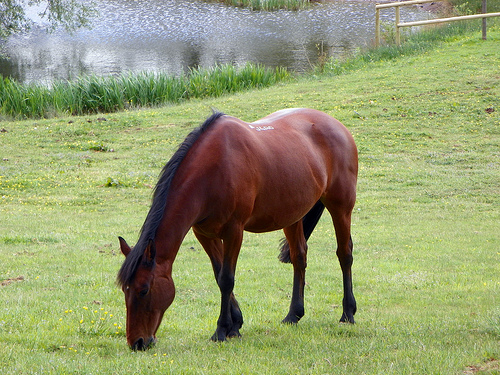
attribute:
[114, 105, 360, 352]
horse — grazing, brown, white, standing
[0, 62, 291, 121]
weeds — tall, long, green, growing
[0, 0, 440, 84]
pond — calm, small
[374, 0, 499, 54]
railing — metal, wood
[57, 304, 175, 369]
flowers — yellow, wild, growing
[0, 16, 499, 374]
grass — green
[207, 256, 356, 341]
markings — black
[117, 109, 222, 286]
mane — black, dark brown, beautiful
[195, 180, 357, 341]
legs — black, crossed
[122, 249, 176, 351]
head — brown, down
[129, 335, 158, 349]
nose — black